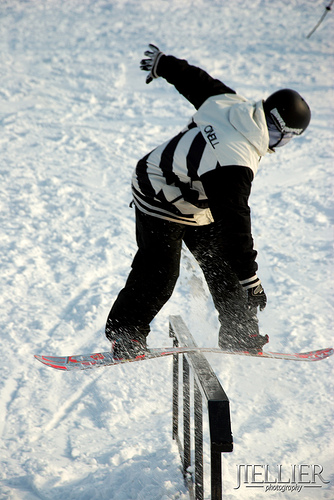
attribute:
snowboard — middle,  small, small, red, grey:
[29, 342, 333, 371]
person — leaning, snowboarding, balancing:
[100, 42, 313, 358]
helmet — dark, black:
[263, 89, 312, 149]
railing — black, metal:
[160, 311, 238, 498]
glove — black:
[243, 278, 270, 312]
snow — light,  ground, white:
[2, 3, 331, 498]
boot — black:
[216, 311, 276, 355]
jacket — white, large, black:
[132, 52, 272, 290]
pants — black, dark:
[106, 207, 265, 327]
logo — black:
[201, 125, 221, 150]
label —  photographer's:
[232, 461, 329, 492]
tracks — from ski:
[3, 261, 111, 428]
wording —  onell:
[202, 123, 220, 149]